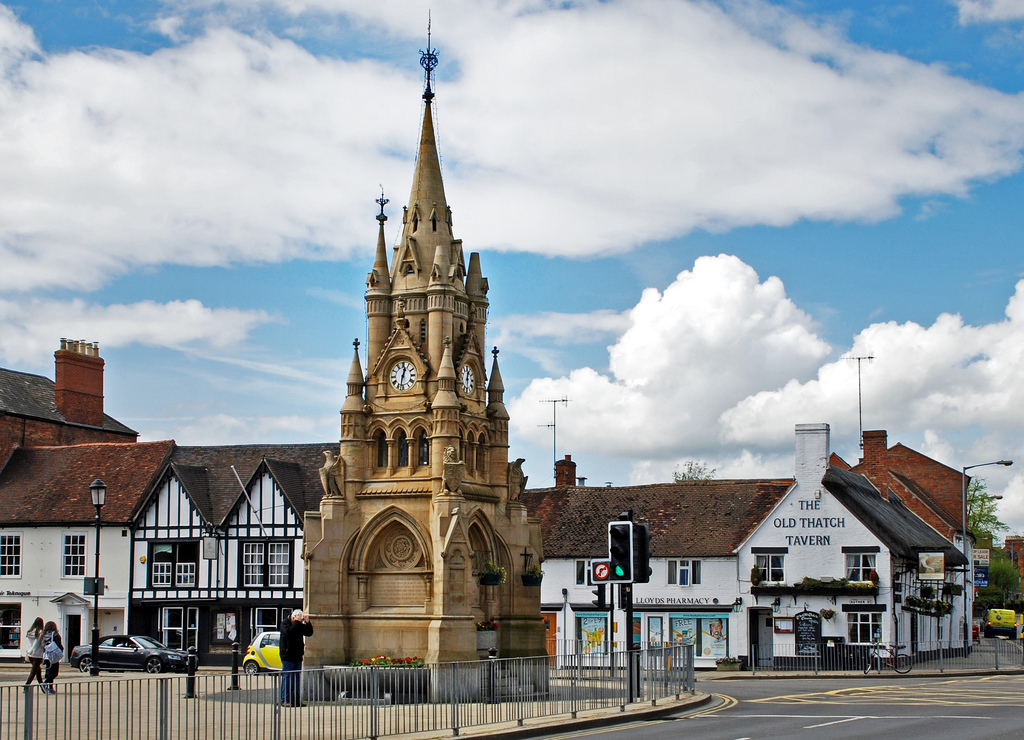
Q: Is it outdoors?
A: Yes, it is outdoors.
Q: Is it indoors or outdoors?
A: It is outdoors.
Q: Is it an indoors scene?
A: No, it is outdoors.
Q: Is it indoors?
A: No, it is outdoors.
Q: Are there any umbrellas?
A: No, there are no umbrellas.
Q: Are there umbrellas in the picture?
A: No, there are no umbrellas.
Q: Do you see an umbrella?
A: No, there are no umbrellas.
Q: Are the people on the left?
A: Yes, the people are on the left of the image.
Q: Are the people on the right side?
A: No, the people are on the left of the image.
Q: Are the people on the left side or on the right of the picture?
A: The people are on the left of the image.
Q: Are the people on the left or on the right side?
A: The people are on the left of the image.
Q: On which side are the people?
A: The people are on the left of the image.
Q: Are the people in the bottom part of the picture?
A: Yes, the people are in the bottom of the image.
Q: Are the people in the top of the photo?
A: No, the people are in the bottom of the image.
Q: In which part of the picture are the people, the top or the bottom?
A: The people are in the bottom of the image.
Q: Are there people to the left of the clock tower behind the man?
A: Yes, there are people to the left of the clock tower.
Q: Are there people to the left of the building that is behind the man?
A: Yes, there are people to the left of the clock tower.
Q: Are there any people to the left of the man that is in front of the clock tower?
A: Yes, there are people to the left of the man.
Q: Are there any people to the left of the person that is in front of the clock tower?
A: Yes, there are people to the left of the man.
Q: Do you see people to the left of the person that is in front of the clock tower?
A: Yes, there are people to the left of the man.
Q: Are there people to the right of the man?
A: No, the people are to the left of the man.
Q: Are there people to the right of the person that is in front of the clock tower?
A: No, the people are to the left of the man.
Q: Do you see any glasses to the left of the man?
A: No, there are people to the left of the man.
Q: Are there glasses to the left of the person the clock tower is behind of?
A: No, there are people to the left of the man.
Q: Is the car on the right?
A: No, the car is on the left of the image.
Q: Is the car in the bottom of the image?
A: Yes, the car is in the bottom of the image.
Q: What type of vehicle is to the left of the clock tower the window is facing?
A: The vehicle is a car.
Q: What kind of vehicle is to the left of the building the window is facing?
A: The vehicle is a car.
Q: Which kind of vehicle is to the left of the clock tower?
A: The vehicle is a car.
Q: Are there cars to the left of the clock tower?
A: Yes, there is a car to the left of the clock tower.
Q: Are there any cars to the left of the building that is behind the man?
A: Yes, there is a car to the left of the clock tower.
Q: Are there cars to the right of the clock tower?
A: No, the car is to the left of the clock tower.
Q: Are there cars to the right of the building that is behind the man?
A: No, the car is to the left of the clock tower.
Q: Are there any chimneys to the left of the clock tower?
A: No, there is a car to the left of the clock tower.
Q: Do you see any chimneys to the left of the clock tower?
A: No, there is a car to the left of the clock tower.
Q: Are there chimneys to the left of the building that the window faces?
A: No, there is a car to the left of the clock tower.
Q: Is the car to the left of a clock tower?
A: Yes, the car is to the left of a clock tower.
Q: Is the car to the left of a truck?
A: No, the car is to the left of a clock tower.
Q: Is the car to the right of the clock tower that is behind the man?
A: No, the car is to the left of the clock tower.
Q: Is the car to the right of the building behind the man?
A: No, the car is to the left of the clock tower.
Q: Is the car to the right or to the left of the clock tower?
A: The car is to the left of the clock tower.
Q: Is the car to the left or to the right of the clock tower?
A: The car is to the left of the clock tower.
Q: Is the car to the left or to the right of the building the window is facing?
A: The car is to the left of the clock tower.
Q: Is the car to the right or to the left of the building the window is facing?
A: The car is to the left of the clock tower.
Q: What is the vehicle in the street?
A: The vehicle is a car.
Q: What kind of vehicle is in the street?
A: The vehicle is a car.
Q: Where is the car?
A: The car is in the street.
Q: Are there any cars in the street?
A: Yes, there is a car in the street.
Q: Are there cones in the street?
A: No, there is a car in the street.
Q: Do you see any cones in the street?
A: No, there is a car in the street.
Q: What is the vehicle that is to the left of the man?
A: The vehicle is a car.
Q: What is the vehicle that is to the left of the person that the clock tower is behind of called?
A: The vehicle is a car.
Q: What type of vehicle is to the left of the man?
A: The vehicle is a car.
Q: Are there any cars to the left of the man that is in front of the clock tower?
A: Yes, there is a car to the left of the man.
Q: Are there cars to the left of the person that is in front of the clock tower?
A: Yes, there is a car to the left of the man.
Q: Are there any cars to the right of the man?
A: No, the car is to the left of the man.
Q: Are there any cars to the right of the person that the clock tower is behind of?
A: No, the car is to the left of the man.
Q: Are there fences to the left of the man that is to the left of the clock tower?
A: No, there is a car to the left of the man.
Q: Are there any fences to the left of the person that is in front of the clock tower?
A: No, there is a car to the left of the man.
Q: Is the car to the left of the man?
A: Yes, the car is to the left of the man.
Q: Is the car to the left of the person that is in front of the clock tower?
A: Yes, the car is to the left of the man.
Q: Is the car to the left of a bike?
A: No, the car is to the left of the man.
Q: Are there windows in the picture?
A: Yes, there is a window.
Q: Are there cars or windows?
A: Yes, there is a window.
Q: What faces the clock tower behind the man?
A: The window faces the clock tower.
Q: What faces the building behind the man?
A: The window faces the clock tower.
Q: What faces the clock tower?
A: The window faces the clock tower.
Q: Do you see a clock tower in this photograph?
A: Yes, there is a clock tower.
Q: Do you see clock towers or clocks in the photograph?
A: Yes, there is a clock tower.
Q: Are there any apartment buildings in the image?
A: No, there are no apartment buildings.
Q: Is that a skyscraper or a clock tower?
A: That is a clock tower.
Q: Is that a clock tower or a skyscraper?
A: That is a clock tower.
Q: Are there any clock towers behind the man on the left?
A: Yes, there is a clock tower behind the man.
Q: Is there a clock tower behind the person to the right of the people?
A: Yes, there is a clock tower behind the man.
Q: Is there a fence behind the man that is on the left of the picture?
A: No, there is a clock tower behind the man.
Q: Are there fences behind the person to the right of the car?
A: No, there is a clock tower behind the man.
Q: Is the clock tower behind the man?
A: Yes, the clock tower is behind the man.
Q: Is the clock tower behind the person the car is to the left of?
A: Yes, the clock tower is behind the man.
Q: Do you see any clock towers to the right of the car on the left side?
A: Yes, there is a clock tower to the right of the car.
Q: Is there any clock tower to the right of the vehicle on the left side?
A: Yes, there is a clock tower to the right of the car.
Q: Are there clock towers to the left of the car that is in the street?
A: No, the clock tower is to the right of the car.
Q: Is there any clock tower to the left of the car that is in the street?
A: No, the clock tower is to the right of the car.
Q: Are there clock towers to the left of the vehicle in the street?
A: No, the clock tower is to the right of the car.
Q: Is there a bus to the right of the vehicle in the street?
A: No, there is a clock tower to the right of the car.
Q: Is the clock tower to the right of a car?
A: Yes, the clock tower is to the right of a car.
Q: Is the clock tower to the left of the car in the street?
A: No, the clock tower is to the right of the car.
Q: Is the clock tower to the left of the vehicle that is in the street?
A: No, the clock tower is to the right of the car.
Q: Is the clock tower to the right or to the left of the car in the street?
A: The clock tower is to the right of the car.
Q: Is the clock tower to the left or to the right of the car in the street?
A: The clock tower is to the right of the car.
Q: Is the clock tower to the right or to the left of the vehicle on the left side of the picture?
A: The clock tower is to the right of the car.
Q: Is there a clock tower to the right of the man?
A: Yes, there is a clock tower to the right of the man.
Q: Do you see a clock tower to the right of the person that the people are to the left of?
A: Yes, there is a clock tower to the right of the man.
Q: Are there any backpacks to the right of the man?
A: No, there is a clock tower to the right of the man.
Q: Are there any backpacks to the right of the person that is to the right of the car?
A: No, there is a clock tower to the right of the man.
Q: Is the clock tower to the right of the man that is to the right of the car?
A: Yes, the clock tower is to the right of the man.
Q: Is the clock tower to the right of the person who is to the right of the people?
A: Yes, the clock tower is to the right of the man.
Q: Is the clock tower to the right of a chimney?
A: No, the clock tower is to the right of the man.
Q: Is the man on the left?
A: Yes, the man is on the left of the image.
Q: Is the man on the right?
A: No, the man is on the left of the image.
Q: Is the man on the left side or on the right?
A: The man is on the left of the image.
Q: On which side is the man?
A: The man is on the left of the image.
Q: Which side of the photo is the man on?
A: The man is on the left of the image.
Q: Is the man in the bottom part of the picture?
A: Yes, the man is in the bottom of the image.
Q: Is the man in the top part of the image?
A: No, the man is in the bottom of the image.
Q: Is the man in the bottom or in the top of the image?
A: The man is in the bottom of the image.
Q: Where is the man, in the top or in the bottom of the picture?
A: The man is in the bottom of the image.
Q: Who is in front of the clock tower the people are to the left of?
A: The man is in front of the clock tower.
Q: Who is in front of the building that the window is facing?
A: The man is in front of the clock tower.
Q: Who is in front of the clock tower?
A: The man is in front of the clock tower.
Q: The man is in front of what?
A: The man is in front of the clock tower.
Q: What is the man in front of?
A: The man is in front of the clock tower.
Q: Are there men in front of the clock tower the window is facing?
A: Yes, there is a man in front of the clock tower.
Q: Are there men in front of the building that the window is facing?
A: Yes, there is a man in front of the clock tower.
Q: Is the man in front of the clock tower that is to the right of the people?
A: Yes, the man is in front of the clock tower.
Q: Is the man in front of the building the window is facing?
A: Yes, the man is in front of the clock tower.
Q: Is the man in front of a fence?
A: No, the man is in front of the clock tower.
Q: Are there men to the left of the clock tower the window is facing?
A: Yes, there is a man to the left of the clock tower.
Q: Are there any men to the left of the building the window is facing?
A: Yes, there is a man to the left of the clock tower.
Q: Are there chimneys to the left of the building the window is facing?
A: No, there is a man to the left of the clock tower.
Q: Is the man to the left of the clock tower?
A: Yes, the man is to the left of the clock tower.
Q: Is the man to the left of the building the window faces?
A: Yes, the man is to the left of the clock tower.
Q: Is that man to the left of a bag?
A: No, the man is to the left of the clock tower.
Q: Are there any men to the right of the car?
A: Yes, there is a man to the right of the car.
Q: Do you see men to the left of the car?
A: No, the man is to the right of the car.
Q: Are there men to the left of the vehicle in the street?
A: No, the man is to the right of the car.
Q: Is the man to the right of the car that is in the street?
A: Yes, the man is to the right of the car.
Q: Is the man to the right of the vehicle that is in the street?
A: Yes, the man is to the right of the car.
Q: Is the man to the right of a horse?
A: No, the man is to the right of the car.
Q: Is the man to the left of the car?
A: No, the man is to the right of the car.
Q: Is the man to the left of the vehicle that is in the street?
A: No, the man is to the right of the car.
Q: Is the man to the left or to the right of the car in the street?
A: The man is to the right of the car.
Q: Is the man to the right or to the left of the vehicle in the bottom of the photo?
A: The man is to the right of the car.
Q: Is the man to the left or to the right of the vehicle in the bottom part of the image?
A: The man is to the right of the car.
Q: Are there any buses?
A: No, there are no buses.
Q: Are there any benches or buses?
A: No, there are no buses or benches.